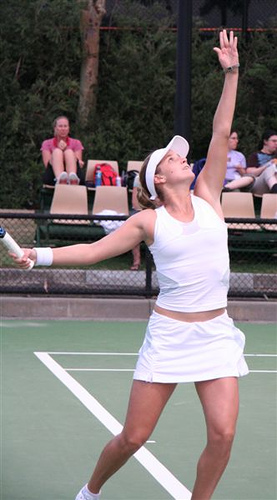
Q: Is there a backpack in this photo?
A: Yes, there is a backpack.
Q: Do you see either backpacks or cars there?
A: Yes, there is a backpack.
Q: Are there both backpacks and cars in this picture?
A: No, there is a backpack but no cars.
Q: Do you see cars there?
A: No, there are no cars.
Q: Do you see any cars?
A: No, there are no cars.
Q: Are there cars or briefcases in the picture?
A: No, there are no cars or briefcases.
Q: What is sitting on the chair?
A: The backpack is sitting on the chair.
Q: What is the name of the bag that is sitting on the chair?
A: The bag is a backpack.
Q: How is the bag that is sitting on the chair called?
A: The bag is a backpack.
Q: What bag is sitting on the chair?
A: The bag is a backpack.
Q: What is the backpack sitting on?
A: The backpack is sitting on the chair.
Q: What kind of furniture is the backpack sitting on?
A: The backpack is sitting on the chair.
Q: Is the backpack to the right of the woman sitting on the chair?
A: Yes, the backpack is sitting on the chair.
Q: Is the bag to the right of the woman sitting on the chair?
A: Yes, the backpack is sitting on the chair.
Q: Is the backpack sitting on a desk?
A: No, the backpack is sitting on the chair.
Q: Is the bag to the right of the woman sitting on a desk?
A: No, the backpack is sitting on the chair.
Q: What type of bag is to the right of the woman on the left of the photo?
A: The bag is a backpack.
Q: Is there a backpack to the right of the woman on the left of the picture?
A: Yes, there is a backpack to the right of the woman.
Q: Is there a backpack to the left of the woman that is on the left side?
A: No, the backpack is to the right of the woman.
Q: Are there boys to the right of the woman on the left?
A: No, there is a backpack to the right of the woman.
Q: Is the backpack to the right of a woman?
A: Yes, the backpack is to the right of a woman.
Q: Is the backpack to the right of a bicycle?
A: No, the backpack is to the right of a woman.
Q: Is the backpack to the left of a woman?
A: No, the backpack is to the right of a woman.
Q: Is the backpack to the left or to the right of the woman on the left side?
A: The backpack is to the right of the woman.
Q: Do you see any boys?
A: No, there are no boys.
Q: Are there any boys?
A: No, there are no boys.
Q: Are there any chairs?
A: Yes, there is a chair.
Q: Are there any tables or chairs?
A: Yes, there is a chair.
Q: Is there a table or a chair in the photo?
A: Yes, there is a chair.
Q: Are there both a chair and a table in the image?
A: No, there is a chair but no tables.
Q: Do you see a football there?
A: No, there are no footballs.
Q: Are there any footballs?
A: No, there are no footballs.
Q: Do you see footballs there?
A: No, there are no footballs.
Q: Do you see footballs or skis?
A: No, there are no footballs or skis.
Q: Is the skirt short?
A: Yes, the skirt is short.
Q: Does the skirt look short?
A: Yes, the skirt is short.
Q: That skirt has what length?
A: The skirt is short.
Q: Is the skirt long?
A: No, the skirt is short.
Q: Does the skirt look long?
A: No, the skirt is short.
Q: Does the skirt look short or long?
A: The skirt is short.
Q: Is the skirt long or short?
A: The skirt is short.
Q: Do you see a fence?
A: Yes, there is a fence.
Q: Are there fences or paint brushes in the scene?
A: Yes, there is a fence.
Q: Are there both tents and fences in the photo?
A: No, there is a fence but no tents.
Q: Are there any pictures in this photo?
A: No, there are no pictures.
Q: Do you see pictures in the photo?
A: No, there are no pictures.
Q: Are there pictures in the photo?
A: No, there are no pictures.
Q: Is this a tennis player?
A: Yes, this is a tennis player.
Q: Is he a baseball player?
A: No, this is a tennis player.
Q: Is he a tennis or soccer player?
A: This is a tennis player.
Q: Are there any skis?
A: No, there are no skis.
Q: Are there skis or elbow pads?
A: No, there are no skis or elbow pads.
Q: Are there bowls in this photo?
A: No, there are no bowls.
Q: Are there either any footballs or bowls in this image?
A: No, there are no bowls or footballs.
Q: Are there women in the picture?
A: Yes, there is a woman.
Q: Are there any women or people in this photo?
A: Yes, there is a woman.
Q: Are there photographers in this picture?
A: No, there are no photographers.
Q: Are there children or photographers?
A: No, there are no photographers or children.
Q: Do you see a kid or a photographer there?
A: No, there are no photographers or children.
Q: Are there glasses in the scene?
A: No, there are no glasses.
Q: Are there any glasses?
A: No, there are no glasses.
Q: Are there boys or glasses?
A: No, there are no glasses or boys.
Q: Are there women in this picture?
A: Yes, there is a woman.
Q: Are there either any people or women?
A: Yes, there is a woman.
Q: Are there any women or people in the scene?
A: Yes, there is a woman.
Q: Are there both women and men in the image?
A: No, there is a woman but no men.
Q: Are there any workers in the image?
A: No, there are no workers.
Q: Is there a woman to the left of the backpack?
A: Yes, there is a woman to the left of the backpack.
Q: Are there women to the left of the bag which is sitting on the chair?
A: Yes, there is a woman to the left of the backpack.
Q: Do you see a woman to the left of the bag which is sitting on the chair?
A: Yes, there is a woman to the left of the backpack.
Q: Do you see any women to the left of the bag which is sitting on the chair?
A: Yes, there is a woman to the left of the backpack.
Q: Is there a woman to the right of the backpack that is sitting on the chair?
A: No, the woman is to the left of the backpack.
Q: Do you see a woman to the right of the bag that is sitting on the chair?
A: No, the woman is to the left of the backpack.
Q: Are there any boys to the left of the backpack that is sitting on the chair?
A: No, there is a woman to the left of the backpack.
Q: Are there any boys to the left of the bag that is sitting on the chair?
A: No, there is a woman to the left of the backpack.